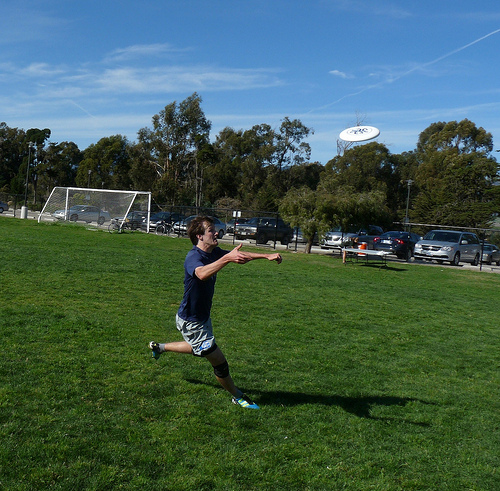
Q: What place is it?
A: It is a field.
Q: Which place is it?
A: It is a field.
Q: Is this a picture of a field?
A: Yes, it is showing a field.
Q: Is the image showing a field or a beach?
A: It is showing a field.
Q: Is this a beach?
A: No, it is a field.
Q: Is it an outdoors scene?
A: Yes, it is outdoors.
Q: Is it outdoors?
A: Yes, it is outdoors.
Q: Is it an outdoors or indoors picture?
A: It is outdoors.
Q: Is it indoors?
A: No, it is outdoors.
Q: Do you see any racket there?
A: No, there are no rackets.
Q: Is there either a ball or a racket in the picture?
A: No, there are no rackets or balls.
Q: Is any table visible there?
A: Yes, there is a table.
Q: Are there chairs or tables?
A: Yes, there is a table.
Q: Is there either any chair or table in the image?
A: Yes, there is a table.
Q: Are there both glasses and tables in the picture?
A: No, there is a table but no glasses.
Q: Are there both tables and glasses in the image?
A: No, there is a table but no glasses.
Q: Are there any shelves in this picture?
A: No, there are no shelves.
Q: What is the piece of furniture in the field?
A: The piece of furniture is a table.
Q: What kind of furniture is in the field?
A: The piece of furniture is a table.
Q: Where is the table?
A: The table is in the field.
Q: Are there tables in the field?
A: Yes, there is a table in the field.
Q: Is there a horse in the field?
A: No, there is a table in the field.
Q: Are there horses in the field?
A: No, there is a table in the field.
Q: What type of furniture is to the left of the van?
A: The piece of furniture is a table.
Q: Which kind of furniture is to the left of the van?
A: The piece of furniture is a table.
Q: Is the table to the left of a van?
A: Yes, the table is to the left of a van.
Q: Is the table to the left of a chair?
A: No, the table is to the left of a van.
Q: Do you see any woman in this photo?
A: No, there are no women.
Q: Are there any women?
A: No, there are no women.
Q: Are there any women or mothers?
A: No, there are no women or mothers.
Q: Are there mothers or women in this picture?
A: No, there are no women or mothers.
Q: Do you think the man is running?
A: Yes, the man is running.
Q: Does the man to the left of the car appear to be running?
A: Yes, the man is running.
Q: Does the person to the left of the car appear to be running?
A: Yes, the man is running.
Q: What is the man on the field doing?
A: The man is running.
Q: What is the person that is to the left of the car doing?
A: The man is running.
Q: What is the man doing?
A: The man is running.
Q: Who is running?
A: The man is running.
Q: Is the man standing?
A: No, the man is running.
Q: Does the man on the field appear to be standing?
A: No, the man is running.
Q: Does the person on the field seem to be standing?
A: No, the man is running.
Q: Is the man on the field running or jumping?
A: The man is running.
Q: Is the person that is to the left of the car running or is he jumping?
A: The man is running.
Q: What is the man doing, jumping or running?
A: The man is running.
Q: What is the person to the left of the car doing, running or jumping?
A: The man is running.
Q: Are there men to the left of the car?
A: Yes, there is a man to the left of the car.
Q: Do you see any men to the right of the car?
A: No, the man is to the left of the car.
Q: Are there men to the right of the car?
A: No, the man is to the left of the car.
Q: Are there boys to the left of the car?
A: No, there is a man to the left of the car.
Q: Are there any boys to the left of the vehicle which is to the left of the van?
A: No, there is a man to the left of the car.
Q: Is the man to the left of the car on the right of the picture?
A: Yes, the man is to the left of the car.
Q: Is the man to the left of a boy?
A: No, the man is to the left of the car.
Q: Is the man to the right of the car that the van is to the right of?
A: No, the man is to the left of the car.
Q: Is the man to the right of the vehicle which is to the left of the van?
A: No, the man is to the left of the car.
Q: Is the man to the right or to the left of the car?
A: The man is to the left of the car.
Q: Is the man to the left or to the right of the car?
A: The man is to the left of the car.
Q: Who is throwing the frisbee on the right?
A: The man is throwing the frisbee.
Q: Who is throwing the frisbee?
A: The man is throwing the frisbee.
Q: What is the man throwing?
A: The man is throwing the frisbee.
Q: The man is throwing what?
A: The man is throwing the frisbee.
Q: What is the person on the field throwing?
A: The man is throwing the frisbee.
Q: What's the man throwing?
A: The man is throwing the frisbee.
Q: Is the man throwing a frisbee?
A: Yes, the man is throwing a frisbee.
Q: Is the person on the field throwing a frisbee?
A: Yes, the man is throwing a frisbee.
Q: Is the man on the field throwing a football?
A: No, the man is throwing a frisbee.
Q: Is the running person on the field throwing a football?
A: No, the man is throwing a frisbee.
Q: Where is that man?
A: The man is on the field.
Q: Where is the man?
A: The man is on the field.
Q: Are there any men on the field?
A: Yes, there is a man on the field.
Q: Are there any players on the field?
A: No, there is a man on the field.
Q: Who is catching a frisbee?
A: The man is catching a frisbee.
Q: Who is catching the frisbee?
A: The man is catching a frisbee.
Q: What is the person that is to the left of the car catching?
A: The man is catching a frisbee.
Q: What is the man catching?
A: The man is catching a frisbee.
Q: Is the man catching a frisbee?
A: Yes, the man is catching a frisbee.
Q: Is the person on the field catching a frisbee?
A: Yes, the man is catching a frisbee.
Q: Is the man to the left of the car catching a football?
A: No, the man is catching a frisbee.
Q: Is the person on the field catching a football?
A: No, the man is catching a frisbee.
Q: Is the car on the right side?
A: Yes, the car is on the right of the image.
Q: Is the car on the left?
A: No, the car is on the right of the image.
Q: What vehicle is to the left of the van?
A: The vehicle is a car.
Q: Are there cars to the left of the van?
A: Yes, there is a car to the left of the van.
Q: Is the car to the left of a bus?
A: No, the car is to the left of the van.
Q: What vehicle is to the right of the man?
A: The vehicle is a car.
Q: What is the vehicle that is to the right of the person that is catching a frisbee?
A: The vehicle is a car.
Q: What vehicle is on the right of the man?
A: The vehicle is a car.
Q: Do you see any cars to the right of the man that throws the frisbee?
A: Yes, there is a car to the right of the man.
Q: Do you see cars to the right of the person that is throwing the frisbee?
A: Yes, there is a car to the right of the man.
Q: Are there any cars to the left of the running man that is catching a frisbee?
A: No, the car is to the right of the man.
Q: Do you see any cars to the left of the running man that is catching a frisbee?
A: No, the car is to the right of the man.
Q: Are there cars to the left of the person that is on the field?
A: No, the car is to the right of the man.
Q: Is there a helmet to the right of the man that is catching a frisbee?
A: No, there is a car to the right of the man.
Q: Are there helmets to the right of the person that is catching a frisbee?
A: No, there is a car to the right of the man.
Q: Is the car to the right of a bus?
A: No, the car is to the right of a man.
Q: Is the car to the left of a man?
A: No, the car is to the right of a man.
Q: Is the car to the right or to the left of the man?
A: The car is to the right of the man.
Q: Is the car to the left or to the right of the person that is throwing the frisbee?
A: The car is to the right of the man.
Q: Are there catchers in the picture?
A: No, there are no catchers.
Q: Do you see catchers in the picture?
A: No, there are no catchers.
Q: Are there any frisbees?
A: Yes, there is a frisbee.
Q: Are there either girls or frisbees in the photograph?
A: Yes, there is a frisbee.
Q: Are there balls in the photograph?
A: No, there are no balls.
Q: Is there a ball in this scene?
A: No, there are no balls.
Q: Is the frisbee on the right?
A: Yes, the frisbee is on the right of the image.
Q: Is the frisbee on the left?
A: No, the frisbee is on the right of the image.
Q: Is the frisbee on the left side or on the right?
A: The frisbee is on the right of the image.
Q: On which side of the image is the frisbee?
A: The frisbee is on the right of the image.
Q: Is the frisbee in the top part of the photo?
A: Yes, the frisbee is in the top of the image.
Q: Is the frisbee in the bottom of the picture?
A: No, the frisbee is in the top of the image.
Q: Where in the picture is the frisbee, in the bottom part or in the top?
A: The frisbee is in the top of the image.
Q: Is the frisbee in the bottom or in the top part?
A: The frisbee is in the top of the image.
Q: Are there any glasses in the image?
A: No, there are no glasses.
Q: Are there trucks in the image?
A: No, there are no trucks.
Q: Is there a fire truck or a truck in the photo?
A: No, there are no trucks or fire trucks.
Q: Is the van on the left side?
A: No, the van is on the right of the image.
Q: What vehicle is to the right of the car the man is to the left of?
A: The vehicle is a van.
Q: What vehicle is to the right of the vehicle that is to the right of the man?
A: The vehicle is a van.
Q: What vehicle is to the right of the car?
A: The vehicle is a van.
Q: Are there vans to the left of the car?
A: No, the van is to the right of the car.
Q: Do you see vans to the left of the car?
A: No, the van is to the right of the car.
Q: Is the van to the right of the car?
A: Yes, the van is to the right of the car.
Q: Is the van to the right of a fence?
A: No, the van is to the right of the car.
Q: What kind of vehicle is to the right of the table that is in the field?
A: The vehicle is a van.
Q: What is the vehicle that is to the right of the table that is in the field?
A: The vehicle is a van.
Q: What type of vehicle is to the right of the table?
A: The vehicle is a van.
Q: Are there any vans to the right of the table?
A: Yes, there is a van to the right of the table.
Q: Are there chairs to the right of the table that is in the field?
A: No, there is a van to the right of the table.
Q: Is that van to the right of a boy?
A: No, the van is to the right of the table.